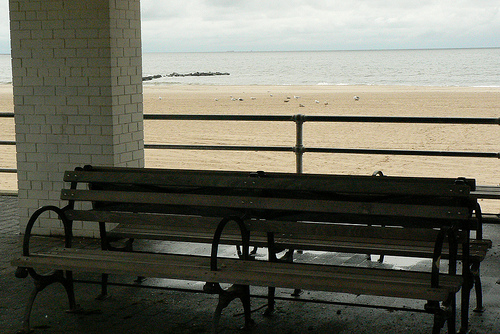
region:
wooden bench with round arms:
[18, 144, 494, 324]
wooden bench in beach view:
[5, 11, 476, 331]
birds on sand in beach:
[201, 93, 261, 111]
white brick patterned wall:
[41, 18, 102, 90]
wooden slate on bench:
[58, 200, 490, 249]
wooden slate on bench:
[54, 187, 486, 222]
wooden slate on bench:
[56, 160, 495, 195]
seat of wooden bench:
[13, 228, 479, 303]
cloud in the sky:
[310, 6, 374, 31]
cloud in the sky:
[182, 11, 234, 42]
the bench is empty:
[29, 144, 475, 314]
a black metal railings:
[144, 99, 444, 192]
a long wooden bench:
[16, 167, 478, 332]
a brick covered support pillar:
[9, 0, 144, 237]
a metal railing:
[0, 111, 498, 220]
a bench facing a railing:
[78, 167, 490, 332]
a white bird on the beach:
[312, 98, 321, 105]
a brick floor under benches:
[0, 194, 493, 331]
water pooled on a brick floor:
[366, 253, 431, 265]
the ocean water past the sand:
[0, 47, 498, 90]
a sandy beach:
[0, 88, 499, 212]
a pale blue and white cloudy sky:
[1, 0, 498, 50]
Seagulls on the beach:
[186, 80, 383, 109]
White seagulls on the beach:
[200, 77, 367, 119]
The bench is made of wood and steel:
[20, 145, 483, 320]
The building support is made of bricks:
[0, 88, 157, 240]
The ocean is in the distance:
[154, 35, 492, 92]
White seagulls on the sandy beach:
[212, 83, 375, 112]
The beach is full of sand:
[372, 88, 489, 116]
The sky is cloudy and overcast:
[182, 3, 476, 45]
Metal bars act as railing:
[153, 92, 498, 196]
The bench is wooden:
[22, 164, 482, 303]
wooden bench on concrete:
[40, 162, 456, 283]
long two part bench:
[37, 165, 466, 267]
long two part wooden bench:
[32, 168, 472, 286]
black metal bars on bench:
[18, 200, 66, 253]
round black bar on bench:
[192, 208, 257, 282]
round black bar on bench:
[415, 223, 468, 280]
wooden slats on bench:
[264, 182, 425, 260]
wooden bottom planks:
[231, 260, 400, 297]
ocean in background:
[217, 32, 401, 87]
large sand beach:
[165, 91, 385, 156]